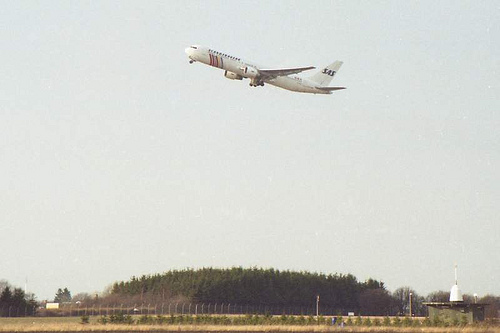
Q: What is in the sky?
A: A airplane.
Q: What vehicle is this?
A: Airplane.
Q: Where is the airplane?
A: In the sky.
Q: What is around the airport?
A: Fence.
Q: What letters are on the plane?
A: SAS.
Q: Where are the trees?
A: In a field.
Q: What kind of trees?
A: Pine trees.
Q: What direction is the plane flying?
A: Left.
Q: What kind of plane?
A: Passenger.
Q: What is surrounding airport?
A: Fence.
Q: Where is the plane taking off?
A: Runway.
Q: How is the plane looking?
A: White.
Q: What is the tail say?
A: SAS.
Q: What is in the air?
A: The airplane.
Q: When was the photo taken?
A: Just after takeoff.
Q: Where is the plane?
A: In the air.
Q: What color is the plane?
A: White.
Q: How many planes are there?
A: One.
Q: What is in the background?
A: Trees.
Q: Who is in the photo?
A: Nobody.